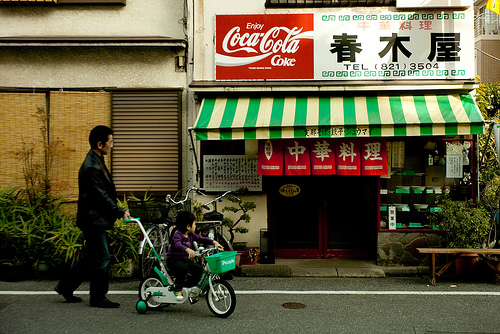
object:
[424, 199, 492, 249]
bush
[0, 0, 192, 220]
building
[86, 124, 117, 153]
black hair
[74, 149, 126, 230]
jacket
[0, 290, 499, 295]
white line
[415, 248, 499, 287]
bench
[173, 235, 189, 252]
arm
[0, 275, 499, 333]
roadway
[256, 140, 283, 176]
banners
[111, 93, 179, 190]
window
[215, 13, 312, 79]
sign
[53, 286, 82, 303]
shoe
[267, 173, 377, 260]
doorway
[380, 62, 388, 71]
black numbers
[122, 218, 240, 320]
bicycle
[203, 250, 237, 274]
basket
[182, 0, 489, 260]
storefront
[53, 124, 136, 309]
man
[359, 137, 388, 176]
sign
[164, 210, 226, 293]
boy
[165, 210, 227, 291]
girl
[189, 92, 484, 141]
awning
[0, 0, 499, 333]
background